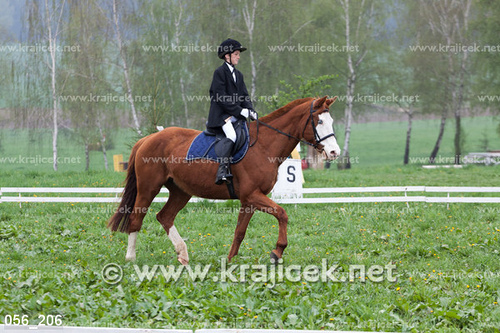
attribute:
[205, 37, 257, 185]
person — woman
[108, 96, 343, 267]
horse — trotting, brown, white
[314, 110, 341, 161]
face — white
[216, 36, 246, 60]
helmet — black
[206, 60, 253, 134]
coat — black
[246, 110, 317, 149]
rein — black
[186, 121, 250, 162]
blanket — blue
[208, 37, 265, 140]
outfit — black, white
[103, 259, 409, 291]
website — advertised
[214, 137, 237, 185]
boot — black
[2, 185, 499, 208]
fence — short, white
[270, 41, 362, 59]
website — watermark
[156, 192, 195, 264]
rear leg — white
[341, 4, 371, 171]
tree — tall, skinny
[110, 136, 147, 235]
tail — hairy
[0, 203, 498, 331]
field — a track, green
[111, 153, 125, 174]
object — orange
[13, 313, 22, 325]
five — number